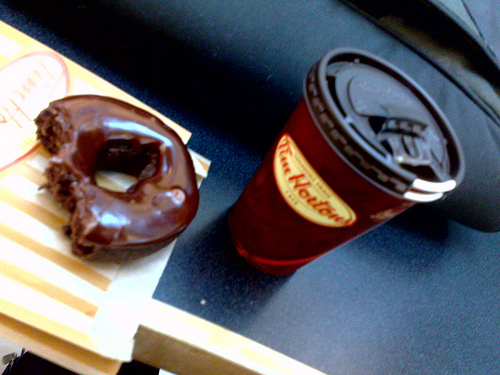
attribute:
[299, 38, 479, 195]
lid — tin, black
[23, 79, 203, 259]
donut — chocolate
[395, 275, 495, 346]
floor — smooth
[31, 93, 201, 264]
cake — brown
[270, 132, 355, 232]
label — yellow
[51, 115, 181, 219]
donut — half eaten, chocolate 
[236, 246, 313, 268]
swirl — red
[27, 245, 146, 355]
papers — light brown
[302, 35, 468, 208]
lid — black 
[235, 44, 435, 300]
bottle — brown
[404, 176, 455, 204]
part — white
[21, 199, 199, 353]
bag — striped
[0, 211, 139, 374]
bag — brown, tan, paper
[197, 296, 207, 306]
spot — tiny, white